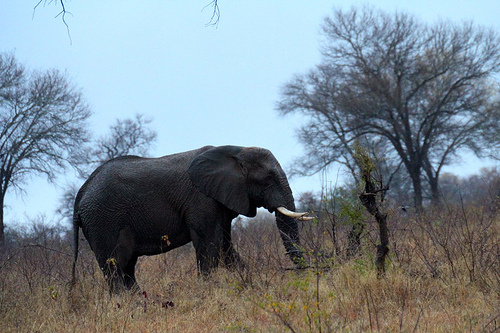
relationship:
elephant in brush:
[60, 143, 308, 312] [300, 197, 498, 259]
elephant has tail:
[60, 143, 308, 312] [63, 219, 79, 298]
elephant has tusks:
[60, 143, 308, 312] [274, 205, 315, 223]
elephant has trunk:
[60, 143, 308, 312] [265, 197, 301, 262]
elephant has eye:
[60, 143, 308, 312] [266, 174, 270, 178]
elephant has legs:
[60, 143, 308, 312] [192, 226, 250, 281]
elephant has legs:
[60, 143, 308, 312] [103, 259, 143, 299]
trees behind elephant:
[278, 8, 497, 227] [60, 143, 308, 312]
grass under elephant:
[12, 274, 493, 325] [60, 143, 308, 312]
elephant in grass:
[60, 143, 308, 312] [12, 274, 493, 325]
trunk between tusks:
[265, 197, 301, 262] [274, 205, 315, 223]